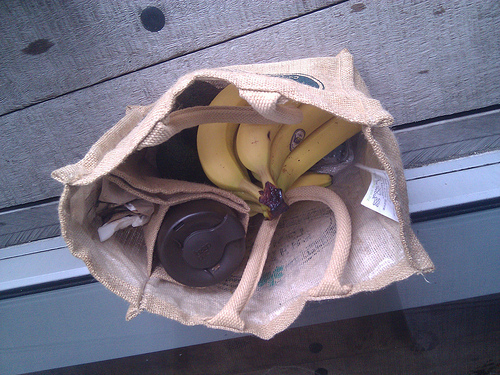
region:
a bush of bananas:
[204, 82, 362, 221]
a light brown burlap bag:
[51, 50, 436, 342]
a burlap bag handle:
[204, 188, 354, 332]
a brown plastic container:
[144, 155, 246, 290]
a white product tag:
[354, 162, 397, 223]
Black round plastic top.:
[151, 200, 248, 289]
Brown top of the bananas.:
[259, 183, 288, 218]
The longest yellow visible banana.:
[199, 78, 260, 199]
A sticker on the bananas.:
[290, 124, 305, 151]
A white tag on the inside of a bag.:
[355, 163, 400, 224]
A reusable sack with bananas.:
[51, 48, 434, 339]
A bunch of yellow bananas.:
[196, 85, 367, 222]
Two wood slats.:
[0, 1, 497, 208]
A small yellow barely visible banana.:
[294, 170, 333, 188]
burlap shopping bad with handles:
[20, 44, 430, 334]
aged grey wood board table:
[0, 1, 497, 248]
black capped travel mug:
[154, 190, 240, 292]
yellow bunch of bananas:
[203, 93, 363, 201]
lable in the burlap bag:
[361, 158, 402, 222]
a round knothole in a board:
[124, 2, 172, 37]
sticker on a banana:
[286, 120, 311, 153]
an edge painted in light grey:
[1, 170, 499, 363]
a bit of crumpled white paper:
[91, 200, 155, 245]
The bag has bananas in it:
[208, 89, 353, 217]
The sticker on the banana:
[285, 127, 315, 155]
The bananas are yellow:
[196, 87, 366, 212]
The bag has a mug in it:
[152, 203, 264, 285]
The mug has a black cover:
[154, 197, 252, 288]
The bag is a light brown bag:
[45, 87, 462, 334]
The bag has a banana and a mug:
[141, 85, 343, 280]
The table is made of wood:
[2, 2, 492, 194]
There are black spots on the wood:
[131, 5, 186, 40]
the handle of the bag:
[221, 187, 351, 314]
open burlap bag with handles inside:
[45, 52, 434, 343]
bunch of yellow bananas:
[197, 91, 365, 221]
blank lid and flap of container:
[158, 197, 248, 291]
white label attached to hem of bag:
[349, 156, 401, 221]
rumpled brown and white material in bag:
[75, 175, 159, 264]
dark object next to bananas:
[125, 75, 222, 187]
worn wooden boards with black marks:
[0, 6, 491, 371]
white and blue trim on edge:
[0, 150, 495, 365]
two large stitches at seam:
[128, 288, 148, 307]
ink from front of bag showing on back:
[257, 209, 337, 295]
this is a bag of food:
[70, 31, 472, 289]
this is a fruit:
[185, 94, 326, 192]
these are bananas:
[194, 94, 309, 176]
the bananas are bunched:
[210, 84, 352, 211]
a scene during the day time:
[1, 3, 484, 374]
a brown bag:
[27, 35, 450, 354]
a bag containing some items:
[48, 43, 444, 357]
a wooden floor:
[3, 0, 498, 200]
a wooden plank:
[4, 1, 497, 166]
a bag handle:
[194, 180, 369, 345]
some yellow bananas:
[181, 64, 372, 233]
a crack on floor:
[0, 0, 368, 139]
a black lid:
[153, 193, 275, 306]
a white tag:
[346, 151, 406, 236]